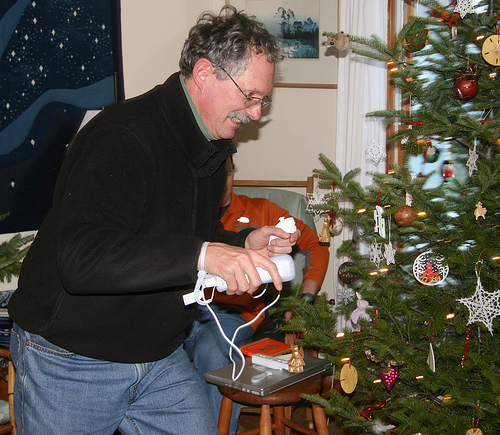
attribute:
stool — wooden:
[215, 387, 347, 429]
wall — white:
[124, 7, 176, 67]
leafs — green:
[415, 287, 441, 307]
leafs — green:
[361, 337, 383, 353]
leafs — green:
[466, 352, 488, 369]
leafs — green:
[472, 236, 488, 262]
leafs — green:
[393, 396, 422, 412]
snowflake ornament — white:
[453, 271, 497, 333]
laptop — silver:
[203, 349, 330, 394]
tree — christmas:
[333, 29, 498, 434]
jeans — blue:
[6, 309, 243, 434]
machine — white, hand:
[199, 253, 295, 291]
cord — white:
[189, 300, 301, 396]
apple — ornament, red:
[446, 47, 483, 103]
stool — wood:
[212, 373, 333, 430]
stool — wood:
[212, 371, 330, 434]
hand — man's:
[238, 222, 300, 254]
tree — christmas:
[251, 9, 496, 433]